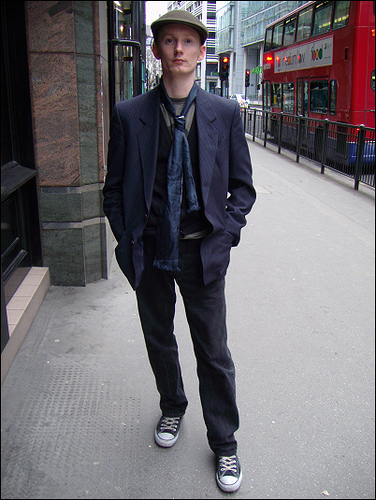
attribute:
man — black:
[87, 70, 262, 349]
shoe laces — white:
[217, 455, 237, 474]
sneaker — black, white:
[211, 452, 242, 493]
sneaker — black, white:
[152, 412, 183, 447]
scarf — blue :
[153, 82, 206, 263]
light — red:
[217, 51, 231, 83]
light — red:
[215, 52, 239, 82]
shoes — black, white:
[149, 410, 176, 451]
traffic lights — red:
[216, 52, 235, 80]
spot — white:
[318, 485, 334, 494]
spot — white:
[351, 286, 362, 294]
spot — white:
[315, 260, 322, 270]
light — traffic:
[221, 51, 231, 78]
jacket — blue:
[102, 83, 255, 289]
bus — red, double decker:
[260, 1, 374, 164]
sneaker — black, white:
[210, 439, 242, 493]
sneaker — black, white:
[156, 402, 185, 452]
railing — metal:
[202, 73, 372, 189]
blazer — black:
[105, 80, 257, 285]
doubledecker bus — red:
[262, 1, 375, 167]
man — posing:
[95, 8, 265, 496]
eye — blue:
[163, 36, 174, 46]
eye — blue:
[183, 36, 193, 44]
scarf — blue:
[153, 77, 208, 275]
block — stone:
[35, 51, 101, 187]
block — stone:
[29, 2, 98, 52]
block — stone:
[38, 192, 104, 215]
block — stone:
[41, 222, 103, 284]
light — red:
[265, 52, 271, 61]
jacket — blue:
[125, 96, 233, 271]